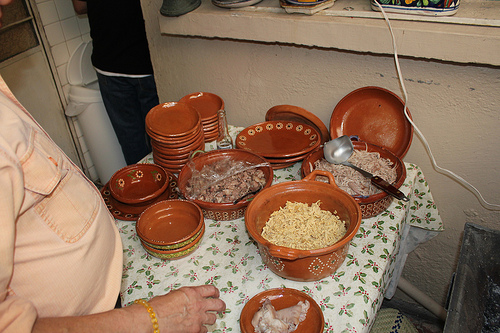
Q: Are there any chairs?
A: No, there are no chairs.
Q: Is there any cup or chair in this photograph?
A: No, there are no chairs or cups.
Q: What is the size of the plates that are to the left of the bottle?
A: The plates are small.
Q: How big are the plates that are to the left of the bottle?
A: The plates are small.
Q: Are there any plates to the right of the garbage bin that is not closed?
A: Yes, there are plates to the right of the garbage can.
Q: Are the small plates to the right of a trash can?
A: Yes, the plates are to the right of a trash can.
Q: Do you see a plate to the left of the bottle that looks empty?
A: Yes, there are plates to the left of the bottle.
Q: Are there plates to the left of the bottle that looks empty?
A: Yes, there are plates to the left of the bottle.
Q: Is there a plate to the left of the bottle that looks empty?
A: Yes, there are plates to the left of the bottle.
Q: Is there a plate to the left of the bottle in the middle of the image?
A: Yes, there are plates to the left of the bottle.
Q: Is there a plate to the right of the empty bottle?
A: No, the plates are to the left of the bottle.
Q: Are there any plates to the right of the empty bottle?
A: No, the plates are to the left of the bottle.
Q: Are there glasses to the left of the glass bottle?
A: No, there are plates to the left of the bottle.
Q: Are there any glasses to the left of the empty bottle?
A: No, there are plates to the left of the bottle.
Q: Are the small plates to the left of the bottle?
A: Yes, the plates are to the left of the bottle.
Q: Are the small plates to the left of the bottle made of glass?
A: Yes, the plates are to the left of the bottle.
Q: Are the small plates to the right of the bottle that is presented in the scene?
A: No, the plates are to the left of the bottle.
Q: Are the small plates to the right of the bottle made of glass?
A: No, the plates are to the left of the bottle.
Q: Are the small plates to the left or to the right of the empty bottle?
A: The plates are to the left of the bottle.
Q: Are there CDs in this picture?
A: No, there are no cds.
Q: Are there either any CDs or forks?
A: No, there are no CDs or forks.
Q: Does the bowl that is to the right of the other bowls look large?
A: Yes, the bowl is large.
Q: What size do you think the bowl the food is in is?
A: The bowl is large.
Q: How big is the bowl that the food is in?
A: The bowl is large.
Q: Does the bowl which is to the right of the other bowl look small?
A: No, the bowl is large.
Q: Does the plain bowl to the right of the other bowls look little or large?
A: The bowl is large.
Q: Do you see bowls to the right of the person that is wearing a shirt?
A: Yes, there is a bowl to the right of the person.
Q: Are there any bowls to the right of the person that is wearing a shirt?
A: Yes, there is a bowl to the right of the person.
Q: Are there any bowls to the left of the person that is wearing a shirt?
A: No, the bowl is to the right of the person.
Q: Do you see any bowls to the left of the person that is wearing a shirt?
A: No, the bowl is to the right of the person.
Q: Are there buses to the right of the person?
A: No, there is a bowl to the right of the person.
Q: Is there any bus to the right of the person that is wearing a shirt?
A: No, there is a bowl to the right of the person.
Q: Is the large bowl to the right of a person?
A: Yes, the bowl is to the right of a person.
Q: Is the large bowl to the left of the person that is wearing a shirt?
A: No, the bowl is to the right of the person.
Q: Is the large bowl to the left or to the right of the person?
A: The bowl is to the right of the person.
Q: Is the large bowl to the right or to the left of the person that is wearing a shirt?
A: The bowl is to the right of the person.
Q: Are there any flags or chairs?
A: No, there are no chairs or flags.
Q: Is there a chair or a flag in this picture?
A: No, there are no chairs or flags.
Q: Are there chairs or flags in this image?
A: No, there are no chairs or flags.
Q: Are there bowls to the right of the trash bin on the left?
A: Yes, there is a bowl to the right of the trash can.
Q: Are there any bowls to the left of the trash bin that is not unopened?
A: No, the bowl is to the right of the garbage can.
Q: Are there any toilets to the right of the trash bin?
A: No, there is a bowl to the right of the trash bin.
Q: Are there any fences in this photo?
A: No, there are no fences.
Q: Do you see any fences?
A: No, there are no fences.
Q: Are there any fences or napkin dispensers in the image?
A: No, there are no fences or napkin dispensers.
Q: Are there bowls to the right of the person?
A: Yes, there is a bowl to the right of the person.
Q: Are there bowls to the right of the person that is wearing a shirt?
A: Yes, there is a bowl to the right of the person.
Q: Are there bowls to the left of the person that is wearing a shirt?
A: No, the bowl is to the right of the person.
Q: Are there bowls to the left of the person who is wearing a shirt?
A: No, the bowl is to the right of the person.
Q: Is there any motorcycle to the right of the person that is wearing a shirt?
A: No, there is a bowl to the right of the person.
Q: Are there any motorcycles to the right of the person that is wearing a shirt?
A: No, there is a bowl to the right of the person.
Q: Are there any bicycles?
A: No, there are no bicycles.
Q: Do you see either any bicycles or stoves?
A: No, there are no bicycles or stoves.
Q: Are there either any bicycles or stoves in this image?
A: No, there are no bicycles or stoves.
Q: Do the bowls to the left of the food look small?
A: Yes, the bowls are small.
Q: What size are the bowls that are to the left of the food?
A: The bowls are small.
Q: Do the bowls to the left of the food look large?
A: No, the bowls are small.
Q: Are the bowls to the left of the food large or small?
A: The bowls are small.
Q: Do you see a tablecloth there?
A: Yes, there is a tablecloth.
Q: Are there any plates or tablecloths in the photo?
A: Yes, there is a tablecloth.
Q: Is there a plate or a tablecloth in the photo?
A: Yes, there is a tablecloth.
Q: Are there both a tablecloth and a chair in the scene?
A: No, there is a tablecloth but no chairs.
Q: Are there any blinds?
A: No, there are no blinds.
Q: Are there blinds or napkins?
A: No, there are no blinds or napkins.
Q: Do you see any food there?
A: Yes, there is food.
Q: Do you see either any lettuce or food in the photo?
A: Yes, there is food.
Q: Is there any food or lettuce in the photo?
A: Yes, there is food.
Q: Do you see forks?
A: No, there are no forks.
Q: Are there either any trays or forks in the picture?
A: No, there are no forks or trays.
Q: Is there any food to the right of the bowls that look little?
A: Yes, there is food to the right of the bowls.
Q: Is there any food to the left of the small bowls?
A: No, the food is to the right of the bowls.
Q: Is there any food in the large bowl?
A: Yes, there is food in the bowl.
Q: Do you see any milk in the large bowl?
A: No, there is food in the bowl.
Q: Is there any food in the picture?
A: Yes, there is food.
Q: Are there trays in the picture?
A: No, there are no trays.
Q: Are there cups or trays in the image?
A: No, there are no trays or cups.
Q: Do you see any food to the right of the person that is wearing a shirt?
A: Yes, there is food to the right of the person.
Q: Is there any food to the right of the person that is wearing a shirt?
A: Yes, there is food to the right of the person.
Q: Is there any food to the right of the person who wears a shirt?
A: Yes, there is food to the right of the person.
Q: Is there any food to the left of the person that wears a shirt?
A: No, the food is to the right of the person.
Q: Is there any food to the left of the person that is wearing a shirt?
A: No, the food is to the right of the person.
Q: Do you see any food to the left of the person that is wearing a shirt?
A: No, the food is to the right of the person.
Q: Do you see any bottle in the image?
A: Yes, there is a bottle.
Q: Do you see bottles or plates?
A: Yes, there is a bottle.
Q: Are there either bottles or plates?
A: Yes, there is a bottle.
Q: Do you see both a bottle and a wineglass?
A: No, there is a bottle but no wine glasses.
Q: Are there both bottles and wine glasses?
A: No, there is a bottle but no wine glasses.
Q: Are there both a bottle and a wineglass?
A: No, there is a bottle but no wine glasses.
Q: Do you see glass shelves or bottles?
A: Yes, there is a glass bottle.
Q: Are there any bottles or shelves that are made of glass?
A: Yes, the bottle is made of glass.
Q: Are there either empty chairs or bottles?
A: Yes, there is an empty bottle.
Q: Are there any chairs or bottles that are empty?
A: Yes, the bottle is empty.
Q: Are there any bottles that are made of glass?
A: Yes, there is a bottle that is made of glass.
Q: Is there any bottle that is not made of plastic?
A: Yes, there is a bottle that is made of glass.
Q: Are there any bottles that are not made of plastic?
A: Yes, there is a bottle that is made of glass.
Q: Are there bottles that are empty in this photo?
A: Yes, there is an empty bottle.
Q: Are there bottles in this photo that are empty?
A: Yes, there is a bottle that is empty.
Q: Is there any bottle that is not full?
A: Yes, there is a empty bottle.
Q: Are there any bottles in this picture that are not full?
A: Yes, there is a empty bottle.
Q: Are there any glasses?
A: No, there are no glasses.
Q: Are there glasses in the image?
A: No, there are no glasses.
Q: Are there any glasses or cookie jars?
A: No, there are no glasses or cookie jars.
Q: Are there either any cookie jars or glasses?
A: No, there are no glasses or cookie jars.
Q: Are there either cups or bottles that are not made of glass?
A: No, there is a bottle but it is made of glass.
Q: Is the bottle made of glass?
A: Yes, the bottle is made of glass.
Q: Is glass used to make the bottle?
A: Yes, the bottle is made of glass.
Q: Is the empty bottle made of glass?
A: Yes, the bottle is made of glass.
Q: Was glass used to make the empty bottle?
A: Yes, the bottle is made of glass.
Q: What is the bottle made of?
A: The bottle is made of glass.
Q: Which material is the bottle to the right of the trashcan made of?
A: The bottle is made of glass.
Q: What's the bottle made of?
A: The bottle is made of glass.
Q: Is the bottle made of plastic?
A: No, the bottle is made of glass.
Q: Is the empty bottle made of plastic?
A: No, the bottle is made of glass.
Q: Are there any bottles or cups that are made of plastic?
A: No, there is a bottle but it is made of glass.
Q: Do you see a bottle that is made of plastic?
A: No, there is a bottle but it is made of glass.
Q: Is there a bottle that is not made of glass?
A: No, there is a bottle but it is made of glass.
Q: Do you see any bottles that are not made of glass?
A: No, there is a bottle but it is made of glass.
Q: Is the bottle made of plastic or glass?
A: The bottle is made of glass.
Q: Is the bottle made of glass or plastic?
A: The bottle is made of glass.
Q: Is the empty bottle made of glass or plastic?
A: The bottle is made of glass.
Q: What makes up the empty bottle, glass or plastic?
A: The bottle is made of glass.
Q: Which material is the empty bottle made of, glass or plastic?
A: The bottle is made of glass.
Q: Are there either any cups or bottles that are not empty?
A: No, there is a bottle but it is empty.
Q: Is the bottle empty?
A: Yes, the bottle is empty.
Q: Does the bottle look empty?
A: Yes, the bottle is empty.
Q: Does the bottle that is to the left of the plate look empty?
A: Yes, the bottle is empty.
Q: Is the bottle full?
A: No, the bottle is empty.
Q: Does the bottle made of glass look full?
A: No, the bottle is empty.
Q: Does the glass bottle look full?
A: No, the bottle is empty.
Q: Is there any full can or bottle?
A: No, there is a bottle but it is empty.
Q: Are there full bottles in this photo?
A: No, there is a bottle but it is empty.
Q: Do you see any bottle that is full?
A: No, there is a bottle but it is empty.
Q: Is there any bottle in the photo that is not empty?
A: No, there is a bottle but it is empty.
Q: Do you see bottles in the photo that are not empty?
A: No, there is a bottle but it is empty.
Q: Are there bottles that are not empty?
A: No, there is a bottle but it is empty.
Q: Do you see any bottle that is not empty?
A: No, there is a bottle but it is empty.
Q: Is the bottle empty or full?
A: The bottle is empty.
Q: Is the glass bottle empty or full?
A: The bottle is empty.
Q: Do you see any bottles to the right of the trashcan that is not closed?
A: Yes, there is a bottle to the right of the garbage can.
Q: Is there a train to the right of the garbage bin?
A: No, there is a bottle to the right of the garbage bin.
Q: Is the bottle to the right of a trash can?
A: Yes, the bottle is to the right of a trash can.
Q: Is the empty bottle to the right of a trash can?
A: Yes, the bottle is to the right of a trash can.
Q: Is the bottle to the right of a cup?
A: No, the bottle is to the right of a trash can.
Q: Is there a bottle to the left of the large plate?
A: Yes, there is a bottle to the left of the plate.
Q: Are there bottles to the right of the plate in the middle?
A: No, the bottle is to the left of the plate.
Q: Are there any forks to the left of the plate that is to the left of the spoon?
A: No, there is a bottle to the left of the plate.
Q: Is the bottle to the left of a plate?
A: Yes, the bottle is to the left of a plate.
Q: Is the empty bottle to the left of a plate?
A: Yes, the bottle is to the left of a plate.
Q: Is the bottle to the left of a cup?
A: No, the bottle is to the left of a plate.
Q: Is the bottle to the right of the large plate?
A: No, the bottle is to the left of the plate.